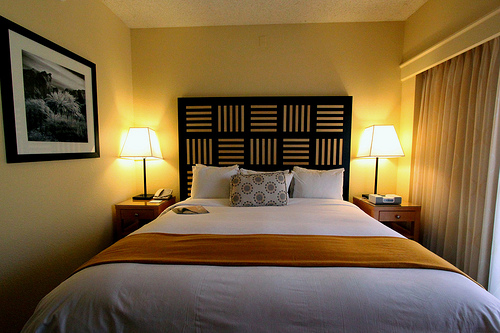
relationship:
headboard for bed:
[177, 95, 352, 201] [34, 176, 498, 328]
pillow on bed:
[224, 168, 289, 206] [15, 95, 498, 330]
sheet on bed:
[58, 231, 477, 270] [15, 95, 498, 330]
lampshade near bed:
[355, 125, 405, 202] [15, 95, 498, 330]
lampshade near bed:
[118, 126, 163, 199] [15, 95, 498, 330]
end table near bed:
[352, 195, 421, 241] [139, 71, 467, 331]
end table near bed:
[115, 196, 175, 239] [139, 71, 467, 331]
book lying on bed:
[173, 200, 211, 217] [33, 129, 476, 331]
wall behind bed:
[136, 22, 409, 95] [15, 95, 498, 330]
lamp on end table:
[355, 124, 403, 199] [352, 197, 420, 241]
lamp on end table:
[119, 128, 164, 198] [115, 197, 170, 239]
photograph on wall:
[4, 61, 71, 163] [0, 0, 132, 330]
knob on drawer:
[393, 212, 402, 219] [378, 209, 415, 224]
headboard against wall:
[172, 93, 354, 198] [131, 19, 405, 200]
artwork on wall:
[0, 12, 102, 160] [0, 0, 132, 330]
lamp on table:
[357, 125, 405, 158] [353, 195, 425, 240]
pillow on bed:
[184, 157, 237, 196] [68, 158, 498, 331]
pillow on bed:
[291, 159, 347, 201] [68, 158, 498, 331]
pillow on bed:
[231, 166, 288, 206] [68, 158, 498, 331]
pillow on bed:
[229, 172, 288, 206] [34, 176, 498, 328]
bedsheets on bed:
[95, 208, 493, 332] [39, 195, 495, 328]